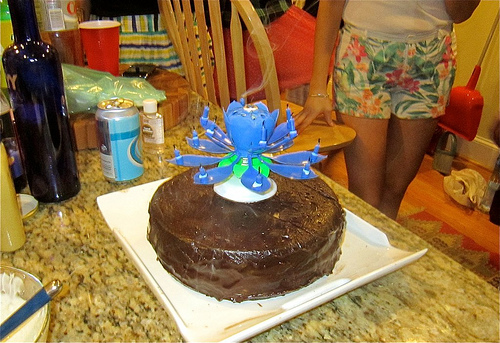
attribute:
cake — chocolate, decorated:
[148, 159, 344, 303]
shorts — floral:
[333, 23, 458, 119]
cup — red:
[80, 21, 120, 78]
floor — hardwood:
[311, 83, 500, 256]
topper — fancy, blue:
[166, 98, 328, 203]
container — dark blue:
[2, 0, 80, 202]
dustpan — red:
[437, 66, 483, 141]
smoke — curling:
[241, 0, 320, 99]